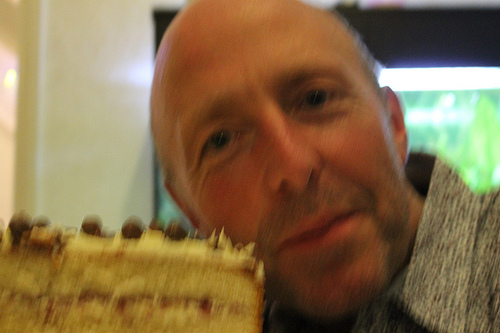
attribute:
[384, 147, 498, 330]
shirt — grey, red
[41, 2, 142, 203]
wall — creme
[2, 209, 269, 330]
cake — sliced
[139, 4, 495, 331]
person — bald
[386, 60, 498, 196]
aquarium — large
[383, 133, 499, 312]
shirt — gray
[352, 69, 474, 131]
tank — fish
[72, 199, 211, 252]
balls — chocolate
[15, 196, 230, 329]
cake — slice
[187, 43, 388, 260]
man — sparkling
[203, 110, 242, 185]
eye — black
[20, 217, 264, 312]
cake — yellow, a slice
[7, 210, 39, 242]
walnut — black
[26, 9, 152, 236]
wall — white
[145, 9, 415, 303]
head — tilted